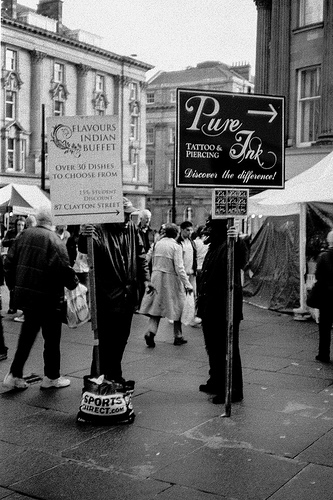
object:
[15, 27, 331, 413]
filter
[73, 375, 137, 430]
bag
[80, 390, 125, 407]
writing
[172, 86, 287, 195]
sign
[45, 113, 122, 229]
sign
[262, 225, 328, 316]
buffet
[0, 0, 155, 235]
buildings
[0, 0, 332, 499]
background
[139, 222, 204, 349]
person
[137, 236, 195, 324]
coat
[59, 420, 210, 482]
tiles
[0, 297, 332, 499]
ground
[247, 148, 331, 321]
tent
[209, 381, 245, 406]
shoes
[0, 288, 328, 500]
street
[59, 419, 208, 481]
cement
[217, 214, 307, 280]
goods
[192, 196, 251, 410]
man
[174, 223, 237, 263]
mask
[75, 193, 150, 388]
person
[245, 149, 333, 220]
canopy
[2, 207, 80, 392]
woman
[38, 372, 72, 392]
shoes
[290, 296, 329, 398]
parlor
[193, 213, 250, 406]
gorilla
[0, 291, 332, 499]
pavement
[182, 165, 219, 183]
imagine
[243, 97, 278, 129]
arrow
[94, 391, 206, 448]
ad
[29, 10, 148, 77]
top